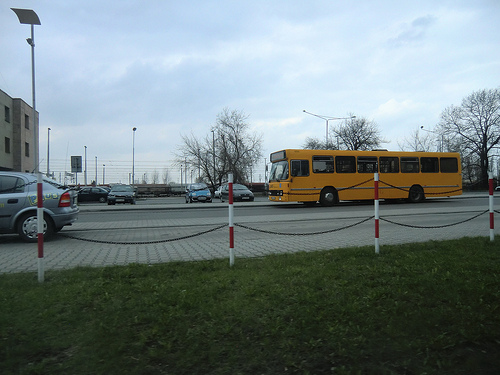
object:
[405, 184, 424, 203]
wheel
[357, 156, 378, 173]
windows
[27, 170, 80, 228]
back end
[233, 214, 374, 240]
chain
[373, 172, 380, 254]
pole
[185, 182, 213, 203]
car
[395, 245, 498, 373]
bushes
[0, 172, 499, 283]
fence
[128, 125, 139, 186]
lights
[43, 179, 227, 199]
chain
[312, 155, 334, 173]
windows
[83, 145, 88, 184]
light pole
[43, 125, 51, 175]
light pole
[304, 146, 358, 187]
light pole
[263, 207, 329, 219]
ground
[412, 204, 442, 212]
ground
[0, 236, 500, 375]
grass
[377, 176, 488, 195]
chain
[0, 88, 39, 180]
building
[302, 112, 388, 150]
trees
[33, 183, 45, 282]
pole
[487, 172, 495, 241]
pole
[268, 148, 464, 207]
bus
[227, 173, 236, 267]
pole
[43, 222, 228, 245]
chain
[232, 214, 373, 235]
chain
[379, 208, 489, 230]
chain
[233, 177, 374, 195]
chain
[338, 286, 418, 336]
green grass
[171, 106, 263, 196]
tree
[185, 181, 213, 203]
blue car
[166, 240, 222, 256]
sidewalk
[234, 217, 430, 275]
bus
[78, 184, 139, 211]
parking lot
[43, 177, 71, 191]
rear windshield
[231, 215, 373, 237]
chain link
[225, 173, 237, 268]
poles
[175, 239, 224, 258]
brick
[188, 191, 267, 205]
parking lot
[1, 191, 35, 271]
lot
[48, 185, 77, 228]
tail end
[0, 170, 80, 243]
car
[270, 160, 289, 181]
windshield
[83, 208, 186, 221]
road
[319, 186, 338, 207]
wheel